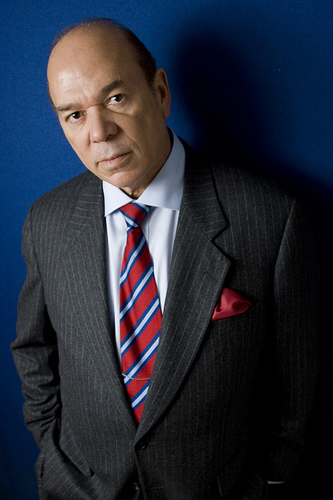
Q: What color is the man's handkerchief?
A: Red.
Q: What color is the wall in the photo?
A: Blue.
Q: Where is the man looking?
A: At the camera.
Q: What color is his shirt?
A: White.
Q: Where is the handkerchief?
A: In his pocket.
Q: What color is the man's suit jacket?
A: Black.